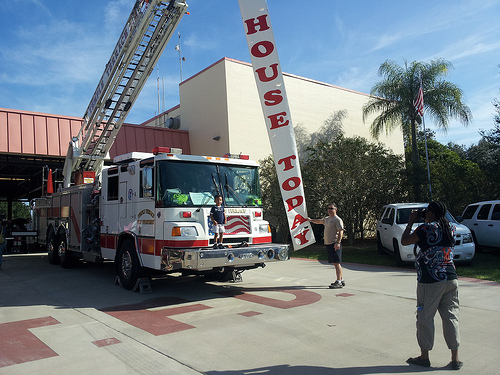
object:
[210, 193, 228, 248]
boy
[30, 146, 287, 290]
truck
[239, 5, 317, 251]
sign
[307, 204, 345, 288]
man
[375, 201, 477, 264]
car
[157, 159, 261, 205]
windshield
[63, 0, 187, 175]
ladder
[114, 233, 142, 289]
tire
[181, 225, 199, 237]
headlight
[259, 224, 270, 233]
headlight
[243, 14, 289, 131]
house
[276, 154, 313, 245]
today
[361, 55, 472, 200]
tree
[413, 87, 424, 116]
flag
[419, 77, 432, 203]
pole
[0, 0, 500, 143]
sky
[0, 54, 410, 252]
house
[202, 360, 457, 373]
shadow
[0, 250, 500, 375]
ground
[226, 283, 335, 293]
shadow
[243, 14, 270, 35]
letter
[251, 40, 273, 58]
letter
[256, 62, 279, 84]
letter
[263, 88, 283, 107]
letter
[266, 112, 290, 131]
letter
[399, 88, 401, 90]
leaves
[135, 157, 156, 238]
door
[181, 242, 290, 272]
bumper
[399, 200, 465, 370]
mother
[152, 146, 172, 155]
lights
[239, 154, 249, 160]
lights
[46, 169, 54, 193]
cone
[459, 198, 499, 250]
car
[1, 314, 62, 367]
letters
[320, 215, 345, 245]
shirt